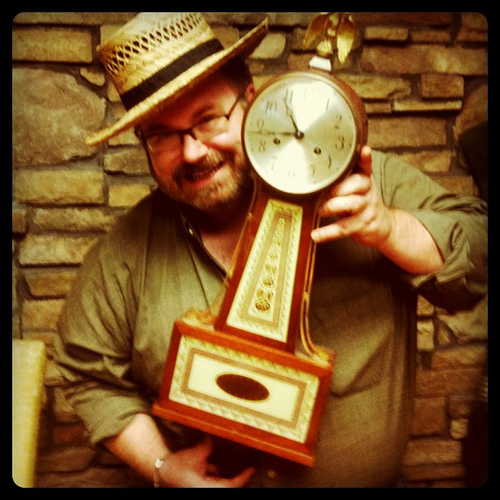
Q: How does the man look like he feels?
A: Happy.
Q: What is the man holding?
A: A clock.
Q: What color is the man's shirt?
A: Green.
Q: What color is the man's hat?
A: Beige.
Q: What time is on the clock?
A: 10:43.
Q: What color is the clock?
A: Brown and gold.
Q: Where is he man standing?
A: In front of a stone wall.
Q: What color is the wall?
A: Beige.